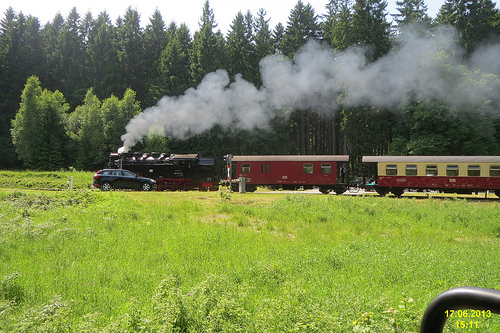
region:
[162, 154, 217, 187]
this is a train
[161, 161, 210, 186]
the train is black in coor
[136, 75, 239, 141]
smoke from the train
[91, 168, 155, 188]
a car is beside the train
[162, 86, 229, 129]
the train is white in color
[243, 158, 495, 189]
the train is long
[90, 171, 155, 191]
the car is back in color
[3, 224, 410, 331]
the grass is long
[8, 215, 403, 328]
the grass is green in color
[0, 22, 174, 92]
the trees are tall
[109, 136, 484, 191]
Train engine two passenger cars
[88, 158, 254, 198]
Car stopped railroad crossing signal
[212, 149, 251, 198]
Crossing signal arm down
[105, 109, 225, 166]
Smokes billows steam engine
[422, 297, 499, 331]
Camera date time stamp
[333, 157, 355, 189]
Conductor stands platform car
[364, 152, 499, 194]
Train passengers enjoy scenery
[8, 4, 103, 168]
Tall pine tree forest background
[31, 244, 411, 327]
Grassy meadow lush bushes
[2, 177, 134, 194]
Dirt road alongside tracks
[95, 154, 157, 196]
blue wagon driving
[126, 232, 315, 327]
green field of grass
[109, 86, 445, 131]
white smoke coming from engine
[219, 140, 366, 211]
red train cart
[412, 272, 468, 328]
rusty brown metal pole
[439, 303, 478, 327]
yellow text time stamp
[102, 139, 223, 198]
black and red portion of train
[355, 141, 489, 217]
yellow and red train couple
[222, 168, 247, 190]
train stop area sign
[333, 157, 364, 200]
conductor standing on train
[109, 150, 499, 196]
Train moving on railroad tracks.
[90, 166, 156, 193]
Car parked beside the train.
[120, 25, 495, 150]
Steam released from the train.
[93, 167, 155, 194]
Black vehicle next to the moving train.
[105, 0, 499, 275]
Train moving in a rural area.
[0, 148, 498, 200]
Train moving on tracks beside a black car.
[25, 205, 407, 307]
Green grass on the ground.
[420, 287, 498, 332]
Black handle to a motor vehicle.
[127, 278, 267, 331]
Weeds on the ground.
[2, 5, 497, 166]
Tall trees with green leaves.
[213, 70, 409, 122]
this is a smoke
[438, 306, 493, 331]
this is date and time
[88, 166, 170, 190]
this is a car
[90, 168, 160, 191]
the car is black in color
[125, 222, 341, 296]
these are grasses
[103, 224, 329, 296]
the grasses are green in color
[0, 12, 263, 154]
these are trees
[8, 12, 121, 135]
the trees are green in color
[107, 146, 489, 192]
this is a train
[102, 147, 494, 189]
the train is long in size